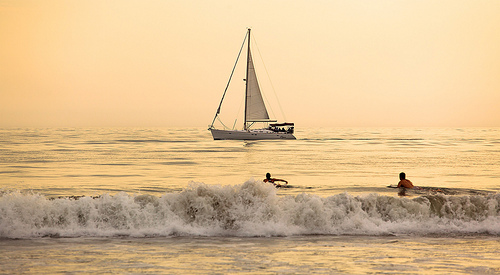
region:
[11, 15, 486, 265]
Some people are at the beach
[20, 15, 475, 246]
Some people are doing some swimming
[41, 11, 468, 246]
Some people are getting very wet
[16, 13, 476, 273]
Some people are enjoying the water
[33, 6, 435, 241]
A sailboat is close to the beach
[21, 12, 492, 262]
The people are getting some exercise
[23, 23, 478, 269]
Some people are out in the daytime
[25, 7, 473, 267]
Some people are on their day off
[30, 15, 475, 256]
Some people are having a great time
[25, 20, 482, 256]
Some people are enjoying their day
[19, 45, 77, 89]
a yellow sky with no clouds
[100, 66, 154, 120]
a yellow sky with no clouds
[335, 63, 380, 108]
a yellow sky with no clouds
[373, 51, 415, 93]
a yellow sky with no clouds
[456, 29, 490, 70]
a yellow sky with no clouds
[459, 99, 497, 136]
a yellow sky with no clouds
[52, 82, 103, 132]
a yellow sky with no clouds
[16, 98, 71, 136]
a yellow sky with no clouds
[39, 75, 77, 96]
a yellow sky with no clouds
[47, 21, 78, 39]
a yellow sky with no clouds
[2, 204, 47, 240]
Ripples in the water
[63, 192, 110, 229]
Ripples in the water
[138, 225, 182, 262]
Ripples in the water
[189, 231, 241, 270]
Ripples in the water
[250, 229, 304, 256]
Ripples in the water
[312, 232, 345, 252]
Ripples in the water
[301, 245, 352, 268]
Ripples in the water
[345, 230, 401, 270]
Ripples in the water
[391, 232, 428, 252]
Ripples in the water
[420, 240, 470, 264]
Ripples in the water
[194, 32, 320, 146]
sailboat on the water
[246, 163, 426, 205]
the people are swimming